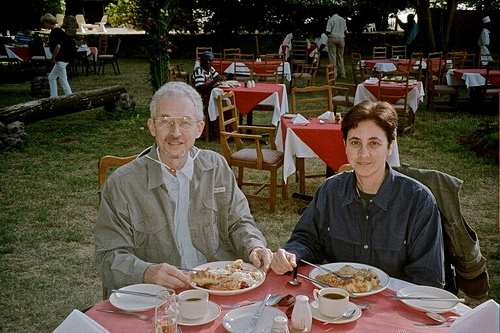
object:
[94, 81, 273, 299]
man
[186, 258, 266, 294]
meal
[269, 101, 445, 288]
lady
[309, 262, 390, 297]
meal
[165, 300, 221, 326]
saucer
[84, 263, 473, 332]
table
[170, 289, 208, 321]
cup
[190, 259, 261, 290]
food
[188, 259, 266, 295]
plate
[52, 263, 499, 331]
tablecloth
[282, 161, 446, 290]
shirt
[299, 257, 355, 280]
silverware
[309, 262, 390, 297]
plate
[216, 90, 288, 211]
chair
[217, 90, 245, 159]
back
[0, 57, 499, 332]
grass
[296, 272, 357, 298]
butterknife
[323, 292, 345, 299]
coffee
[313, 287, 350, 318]
cup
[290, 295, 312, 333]
salt shaker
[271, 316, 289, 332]
pepper shaker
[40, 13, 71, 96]
woman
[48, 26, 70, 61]
shirt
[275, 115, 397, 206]
table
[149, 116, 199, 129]
glasses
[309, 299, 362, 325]
saucer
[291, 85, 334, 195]
chair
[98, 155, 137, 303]
chair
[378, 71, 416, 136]
chair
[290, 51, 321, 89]
chair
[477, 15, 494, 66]
person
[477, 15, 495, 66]
chef's uniform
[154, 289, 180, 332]
glass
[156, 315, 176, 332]
water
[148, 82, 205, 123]
hair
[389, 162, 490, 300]
vest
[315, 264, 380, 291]
food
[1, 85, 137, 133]
log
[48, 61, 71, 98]
pants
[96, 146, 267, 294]
shirt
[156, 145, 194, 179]
collar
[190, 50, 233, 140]
person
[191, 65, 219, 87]
shirt